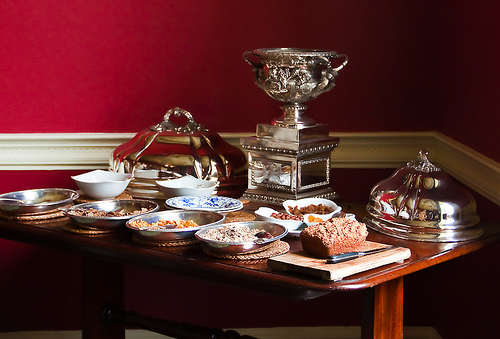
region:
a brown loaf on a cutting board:
[299, 217, 368, 258]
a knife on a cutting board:
[328, 244, 396, 262]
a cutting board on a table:
[267, 237, 410, 286]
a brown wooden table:
[0, 192, 497, 337]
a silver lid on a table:
[365, 146, 482, 241]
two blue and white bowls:
[162, 190, 238, 215]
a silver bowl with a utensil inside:
[2, 187, 79, 216]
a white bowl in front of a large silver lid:
[68, 170, 129, 198]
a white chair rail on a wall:
[0, 126, 433, 173]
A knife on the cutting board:
[328, 245, 398, 265]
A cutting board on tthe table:
[268, 238, 410, 281]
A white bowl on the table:
[73, 169, 131, 196]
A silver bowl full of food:
[60, 197, 157, 226]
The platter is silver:
[367, 148, 484, 240]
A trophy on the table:
[241, 47, 348, 205]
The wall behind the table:
[1, 1, 498, 161]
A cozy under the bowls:
[202, 237, 289, 258]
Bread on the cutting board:
[301, 214, 368, 254]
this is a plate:
[205, 215, 283, 255]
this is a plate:
[130, 210, 214, 238]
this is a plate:
[77, 196, 156, 223]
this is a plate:
[0, 179, 74, 216]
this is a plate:
[75, 162, 139, 202]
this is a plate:
[160, 172, 220, 199]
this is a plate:
[259, 201, 316, 233]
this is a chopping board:
[273, 245, 414, 285]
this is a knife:
[329, 238, 423, 264]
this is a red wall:
[0, 4, 499, 136]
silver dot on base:
[286, 148, 293, 155]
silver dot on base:
[281, 146, 286, 155]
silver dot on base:
[268, 145, 276, 151]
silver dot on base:
[250, 143, 260, 153]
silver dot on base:
[298, 148, 306, 154]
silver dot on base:
[301, 145, 311, 153]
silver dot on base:
[312, 145, 319, 153]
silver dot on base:
[323, 143, 330, 149]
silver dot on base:
[253, 145, 260, 152]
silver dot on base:
[331, 188, 336, 194]